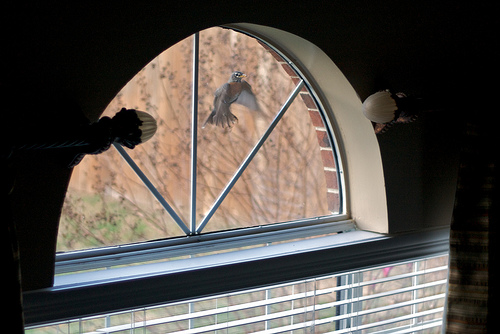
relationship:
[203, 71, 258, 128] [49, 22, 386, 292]
bird outside window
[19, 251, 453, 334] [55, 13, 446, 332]
blinds covering window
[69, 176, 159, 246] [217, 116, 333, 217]
tree outside window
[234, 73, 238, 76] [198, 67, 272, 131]
eye of bird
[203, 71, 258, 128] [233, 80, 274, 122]
bird flapping wing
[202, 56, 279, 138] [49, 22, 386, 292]
bird outside window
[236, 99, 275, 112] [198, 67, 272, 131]
wing of bird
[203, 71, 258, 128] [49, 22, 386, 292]
bird near window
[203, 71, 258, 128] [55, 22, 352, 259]
bird at window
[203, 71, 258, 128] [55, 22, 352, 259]
bird outside window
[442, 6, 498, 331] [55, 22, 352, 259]
curtain near window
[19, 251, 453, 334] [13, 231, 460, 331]
blinds on window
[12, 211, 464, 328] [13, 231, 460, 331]
trim around window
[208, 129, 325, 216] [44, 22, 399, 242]
tree outside window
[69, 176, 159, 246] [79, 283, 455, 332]
tree outside window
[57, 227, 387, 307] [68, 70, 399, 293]
sil under window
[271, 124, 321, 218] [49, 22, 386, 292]
branches through window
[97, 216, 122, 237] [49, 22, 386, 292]
leaves through window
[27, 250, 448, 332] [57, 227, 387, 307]
window under sil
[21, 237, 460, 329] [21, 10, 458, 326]
blinds on window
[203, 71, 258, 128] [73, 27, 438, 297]
bird outside window